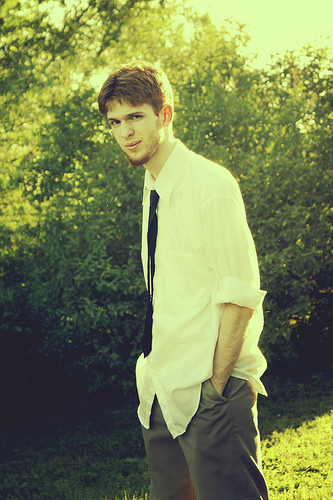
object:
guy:
[98, 62, 269, 498]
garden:
[0, 0, 332, 500]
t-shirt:
[134, 138, 268, 439]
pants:
[139, 376, 268, 500]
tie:
[142, 190, 160, 358]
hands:
[194, 304, 254, 450]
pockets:
[191, 378, 231, 453]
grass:
[1, 375, 331, 499]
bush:
[229, 48, 332, 364]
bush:
[2, 19, 139, 395]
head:
[98, 60, 174, 167]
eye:
[128, 114, 143, 121]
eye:
[110, 118, 120, 125]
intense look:
[107, 113, 143, 129]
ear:
[161, 104, 173, 127]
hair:
[98, 62, 173, 117]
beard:
[118, 116, 162, 165]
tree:
[1, 0, 219, 414]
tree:
[227, 0, 332, 368]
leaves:
[1, 1, 167, 139]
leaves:
[248, 0, 332, 225]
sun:
[250, 0, 332, 50]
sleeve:
[201, 193, 267, 311]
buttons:
[144, 177, 178, 440]